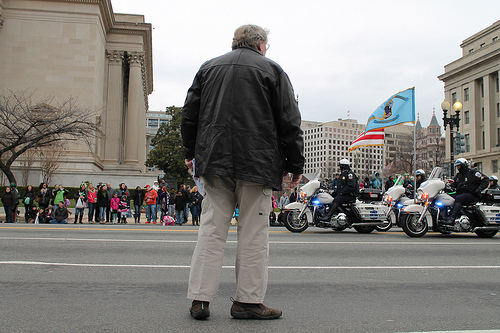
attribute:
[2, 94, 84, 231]
tree — bare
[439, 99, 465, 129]
streetlamp — on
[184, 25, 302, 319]
man — standing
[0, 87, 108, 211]
tree —  leafless.